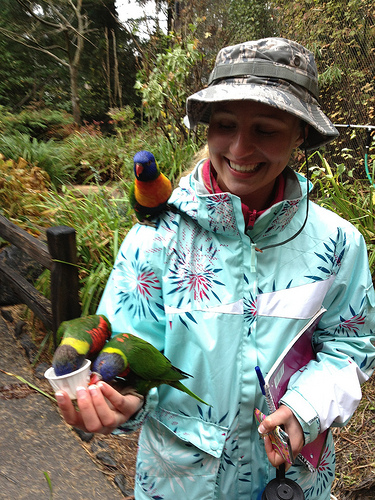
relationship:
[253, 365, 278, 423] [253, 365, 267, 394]
pen has a blue cap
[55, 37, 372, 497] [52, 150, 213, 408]
woman with three birds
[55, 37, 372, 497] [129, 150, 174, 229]
woman with bird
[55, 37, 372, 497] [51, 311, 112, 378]
woman with bird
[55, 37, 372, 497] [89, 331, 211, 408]
woman with bird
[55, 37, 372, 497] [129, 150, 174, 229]
woman with parakeet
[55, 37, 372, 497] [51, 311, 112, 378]
woman with parakeet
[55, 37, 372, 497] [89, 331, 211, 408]
woman with parakeet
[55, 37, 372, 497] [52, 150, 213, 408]
woman with three parakeets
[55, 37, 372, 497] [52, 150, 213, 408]
scientist experimenting with three birds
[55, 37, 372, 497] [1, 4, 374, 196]
woman in woods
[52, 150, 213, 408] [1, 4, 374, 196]
three birds are in woods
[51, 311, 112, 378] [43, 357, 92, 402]
bird drinking water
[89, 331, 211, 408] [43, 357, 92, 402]
bird drinking water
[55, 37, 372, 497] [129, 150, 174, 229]
woman walking with pet parakeet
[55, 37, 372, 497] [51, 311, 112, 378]
woman walking with pet parakeet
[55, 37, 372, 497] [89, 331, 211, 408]
woman walking with pet parakeet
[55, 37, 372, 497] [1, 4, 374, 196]
woman enjoying wilderness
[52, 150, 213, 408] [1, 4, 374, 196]
three parakeets are enjoying wilderness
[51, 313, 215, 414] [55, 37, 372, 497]
parrots are being held by woman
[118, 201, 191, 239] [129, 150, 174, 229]
shoulder holding parrot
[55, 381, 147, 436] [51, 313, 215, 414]
hand holding parrots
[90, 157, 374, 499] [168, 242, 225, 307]
jacket has floral print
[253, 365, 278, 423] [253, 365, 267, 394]
pen has blue cap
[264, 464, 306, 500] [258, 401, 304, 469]
water bottle hanging from hand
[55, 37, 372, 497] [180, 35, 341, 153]
lady wearing hat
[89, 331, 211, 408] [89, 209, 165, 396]
bird on ladys arm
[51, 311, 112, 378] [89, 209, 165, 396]
bird on ladys arm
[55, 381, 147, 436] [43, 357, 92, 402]
hand holding object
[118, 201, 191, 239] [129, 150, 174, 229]
shoulder holding bird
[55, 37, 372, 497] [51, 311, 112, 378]
lady looking at bird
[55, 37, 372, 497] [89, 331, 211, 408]
lady looking at bird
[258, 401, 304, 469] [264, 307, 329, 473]
hand holding notebook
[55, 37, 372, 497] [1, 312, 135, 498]
lady on a street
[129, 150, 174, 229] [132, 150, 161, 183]
bird has blue head